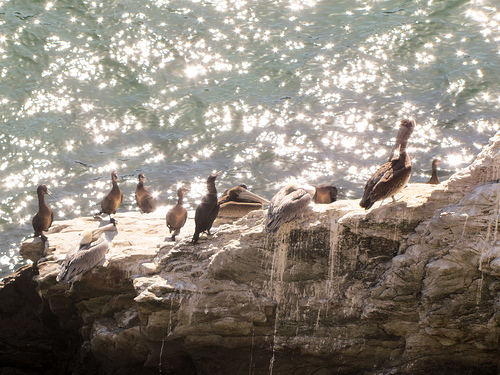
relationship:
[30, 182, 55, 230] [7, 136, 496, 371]
bird on rock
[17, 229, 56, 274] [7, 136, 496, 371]
bird on rock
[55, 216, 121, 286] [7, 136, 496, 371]
bird on rock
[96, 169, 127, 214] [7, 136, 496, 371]
bird on rock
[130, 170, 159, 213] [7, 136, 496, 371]
bird on rock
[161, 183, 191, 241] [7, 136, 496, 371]
bird on rock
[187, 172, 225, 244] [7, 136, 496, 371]
bird on rock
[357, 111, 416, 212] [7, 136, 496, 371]
bird on rock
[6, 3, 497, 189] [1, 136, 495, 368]
water beside rocks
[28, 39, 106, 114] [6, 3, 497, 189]
sunlight on water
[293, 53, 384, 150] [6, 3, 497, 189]
sunlight on water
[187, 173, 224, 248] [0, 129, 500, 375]
bird on rock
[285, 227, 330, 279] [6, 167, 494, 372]
stain on rock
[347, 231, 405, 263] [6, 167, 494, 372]
stain on rock